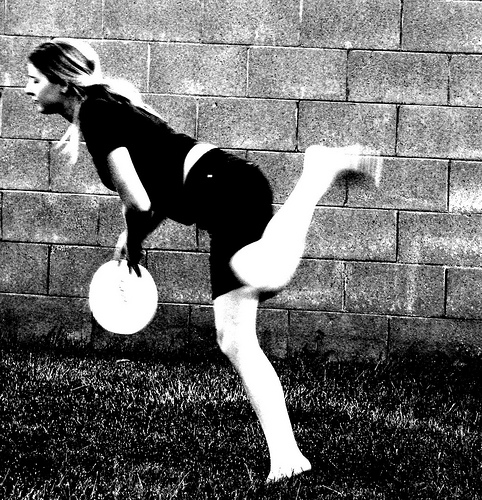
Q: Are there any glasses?
A: No, there are no glasses.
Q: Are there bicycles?
A: No, there are no bicycles.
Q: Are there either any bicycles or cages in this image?
A: No, there are no bicycles or cages.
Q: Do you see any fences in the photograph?
A: No, there are no fences.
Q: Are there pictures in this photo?
A: No, there are no pictures.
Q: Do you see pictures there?
A: No, there are no pictures.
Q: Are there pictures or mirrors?
A: No, there are no pictures or mirrors.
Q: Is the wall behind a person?
A: Yes, the wall is behind a person.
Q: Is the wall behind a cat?
A: No, the wall is behind a person.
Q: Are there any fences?
A: No, there are no fences.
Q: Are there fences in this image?
A: No, there are no fences.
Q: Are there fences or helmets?
A: No, there are no fences or helmets.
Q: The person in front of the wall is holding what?
A: The person is holding the frisbee.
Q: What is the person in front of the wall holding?
A: The person is holding the frisbee.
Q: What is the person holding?
A: The person is holding the frisbee.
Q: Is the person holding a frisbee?
A: Yes, the person is holding a frisbee.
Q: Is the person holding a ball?
A: No, the person is holding a frisbee.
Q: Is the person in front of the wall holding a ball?
A: No, the person is holding a frisbee.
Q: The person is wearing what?
A: The person is wearing shorts.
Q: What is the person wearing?
A: The person is wearing shorts.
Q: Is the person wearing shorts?
A: Yes, the person is wearing shorts.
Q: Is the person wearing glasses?
A: No, the person is wearing shorts.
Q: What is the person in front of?
A: The person is in front of the wall.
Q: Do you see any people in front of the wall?
A: Yes, there is a person in front of the wall.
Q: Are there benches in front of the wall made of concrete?
A: No, there is a person in front of the wall.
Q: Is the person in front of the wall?
A: Yes, the person is in front of the wall.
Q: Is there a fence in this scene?
A: No, there are no fences.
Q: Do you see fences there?
A: No, there are no fences.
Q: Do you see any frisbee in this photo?
A: Yes, there is a frisbee.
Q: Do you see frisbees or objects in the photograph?
A: Yes, there is a frisbee.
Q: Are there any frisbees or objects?
A: Yes, there is a frisbee.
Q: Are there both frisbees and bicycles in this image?
A: No, there is a frisbee but no bikes.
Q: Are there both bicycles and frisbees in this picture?
A: No, there is a frisbee but no bikes.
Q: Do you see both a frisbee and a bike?
A: No, there is a frisbee but no bikes.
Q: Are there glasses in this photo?
A: No, there are no glasses.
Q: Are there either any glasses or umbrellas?
A: No, there are no glasses or umbrellas.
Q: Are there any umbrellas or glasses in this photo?
A: No, there are no glasses or umbrellas.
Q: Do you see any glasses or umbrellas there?
A: No, there are no glasses or umbrellas.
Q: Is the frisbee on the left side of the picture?
A: Yes, the frisbee is on the left of the image.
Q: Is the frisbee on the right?
A: No, the frisbee is on the left of the image.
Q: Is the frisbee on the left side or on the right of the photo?
A: The frisbee is on the left of the image.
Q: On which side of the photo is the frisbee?
A: The frisbee is on the left of the image.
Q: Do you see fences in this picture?
A: No, there are no fences.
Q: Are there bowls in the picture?
A: No, there are no bowls.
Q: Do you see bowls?
A: No, there are no bowls.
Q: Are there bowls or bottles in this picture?
A: No, there are no bowls or bottles.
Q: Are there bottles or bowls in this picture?
A: No, there are no bowls or bottles.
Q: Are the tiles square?
A: Yes, the tiles are square.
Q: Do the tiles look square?
A: Yes, the tiles are square.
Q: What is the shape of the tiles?
A: The tiles are square.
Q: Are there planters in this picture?
A: No, there are no planters.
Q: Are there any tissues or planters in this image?
A: No, there are no planters or tissues.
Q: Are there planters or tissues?
A: No, there are no planters or tissues.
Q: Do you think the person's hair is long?
A: Yes, the hair is long.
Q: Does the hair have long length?
A: Yes, the hair is long.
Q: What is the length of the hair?
A: The hair is long.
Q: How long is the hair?
A: The hair is long.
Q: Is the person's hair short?
A: No, the hair is long.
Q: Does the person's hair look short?
A: No, the hair is long.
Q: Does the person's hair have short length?
A: No, the hair is long.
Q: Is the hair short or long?
A: The hair is long.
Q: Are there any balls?
A: No, there are no balls.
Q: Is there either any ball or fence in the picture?
A: No, there are no balls or fences.